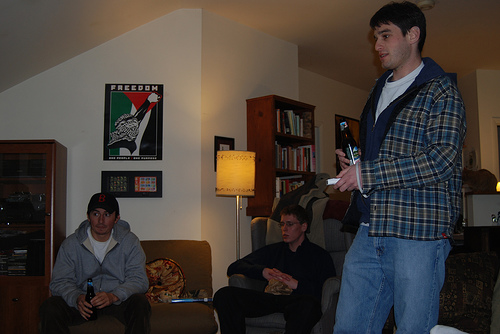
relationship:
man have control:
[334, 0, 489, 332] [326, 170, 348, 188]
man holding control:
[334, 0, 489, 332] [326, 170, 348, 188]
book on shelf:
[289, 106, 298, 135] [274, 130, 311, 146]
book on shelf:
[295, 139, 318, 172] [274, 169, 324, 179]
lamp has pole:
[210, 142, 262, 269] [231, 192, 241, 266]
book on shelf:
[279, 113, 293, 137] [244, 92, 326, 213]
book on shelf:
[287, 145, 298, 170] [264, 163, 327, 182]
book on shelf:
[287, 145, 294, 170] [274, 165, 315, 177]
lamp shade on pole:
[214, 148, 256, 196] [234, 193, 243, 260]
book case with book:
[246, 89, 331, 224] [278, 145, 300, 167]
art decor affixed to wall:
[106, 82, 162, 159] [0, 7, 201, 239]